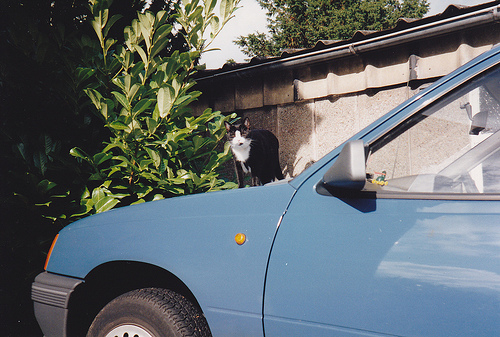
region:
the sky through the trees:
[194, 3, 256, 66]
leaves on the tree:
[94, 29, 215, 194]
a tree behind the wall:
[266, 7, 373, 52]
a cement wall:
[221, 88, 408, 155]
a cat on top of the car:
[140, 87, 335, 304]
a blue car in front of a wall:
[28, 45, 499, 327]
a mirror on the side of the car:
[317, 137, 380, 195]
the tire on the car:
[80, 288, 198, 332]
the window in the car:
[358, 80, 493, 191]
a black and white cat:
[220, 114, 281, 186]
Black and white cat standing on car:
[222, 119, 284, 186]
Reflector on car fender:
[230, 231, 248, 246]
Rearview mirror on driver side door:
[318, 140, 370, 192]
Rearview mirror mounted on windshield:
[461, 99, 493, 137]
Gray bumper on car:
[29, 271, 83, 336]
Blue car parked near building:
[27, 38, 496, 333]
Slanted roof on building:
[189, 0, 498, 82]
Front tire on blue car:
[72, 283, 212, 335]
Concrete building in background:
[185, 3, 497, 187]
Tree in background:
[234, 0, 431, 62]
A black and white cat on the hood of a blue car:
[216, 112, 300, 203]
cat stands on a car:
[201, 100, 304, 205]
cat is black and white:
[213, 113, 291, 188]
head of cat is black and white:
[218, 114, 258, 151]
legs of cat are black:
[231, 168, 276, 190]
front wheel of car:
[76, 268, 213, 335]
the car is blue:
[25, 47, 499, 335]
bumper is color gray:
[23, 269, 82, 335]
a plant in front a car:
[1, 0, 418, 335]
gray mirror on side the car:
[303, 125, 383, 212]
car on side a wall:
[3, 0, 499, 335]